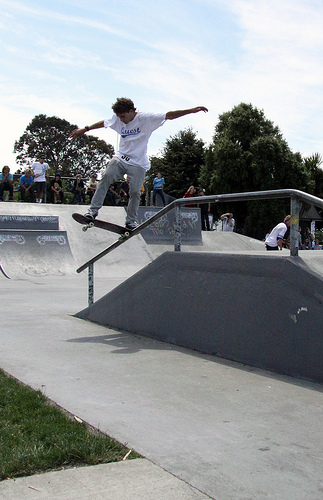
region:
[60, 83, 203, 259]
a man skateboarding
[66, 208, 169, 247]
a skateboard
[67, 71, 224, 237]
a person wearing a watch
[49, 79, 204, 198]
a person wearing a white shirt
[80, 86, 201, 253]
a person wearing grey pants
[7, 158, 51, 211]
a person wearing a blue shirt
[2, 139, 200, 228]
people sitting down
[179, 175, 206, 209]
a person wearing a red shirt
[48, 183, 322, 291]
a skateboarding rail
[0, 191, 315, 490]
silver cemented skateboarding park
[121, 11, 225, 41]
Sky is blue color.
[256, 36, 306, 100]
Clouds are white color.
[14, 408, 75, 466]
Grass are green color.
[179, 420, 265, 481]
Ground is grey color.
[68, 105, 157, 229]
One boy is doing skating tricks.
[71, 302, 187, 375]
Shadow falls on the ground.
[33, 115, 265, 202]
Trees are found behind the ground.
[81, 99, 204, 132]
Skating boy is wearing white shirt.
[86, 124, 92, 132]
Skating boy is wearing black watch.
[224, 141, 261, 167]
Trees are green color.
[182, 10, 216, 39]
part of the sky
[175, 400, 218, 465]
part of a footpath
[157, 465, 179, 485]
part of a line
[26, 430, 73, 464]
part of some grass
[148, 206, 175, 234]
part of a metal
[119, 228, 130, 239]
wheels of a skateboard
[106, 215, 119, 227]
edge of a skateboard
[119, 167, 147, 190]
part of a trouser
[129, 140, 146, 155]
part of a white top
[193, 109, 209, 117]
part of the left hand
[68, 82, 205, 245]
skater doing a trick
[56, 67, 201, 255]
skater grinding on a rail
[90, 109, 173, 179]
shirt with blue lettering on it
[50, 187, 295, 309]
pole with skateboard grinding on it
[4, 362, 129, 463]
green grass next to cement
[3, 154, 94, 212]
people watching in the background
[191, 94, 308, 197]
trees in the background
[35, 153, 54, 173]
man in glasses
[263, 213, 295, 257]
skater riding on his board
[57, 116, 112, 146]
watch on skater's hand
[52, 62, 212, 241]
boy is grinding down railing